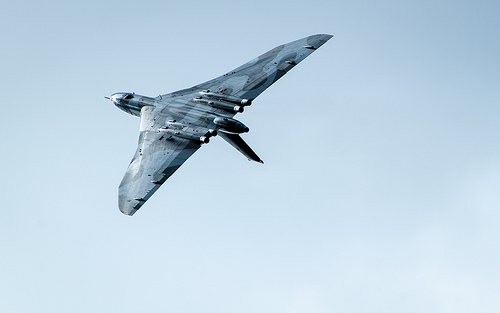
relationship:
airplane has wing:
[104, 34, 334, 216] [117, 116, 213, 217]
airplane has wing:
[104, 34, 334, 216] [191, 34, 332, 110]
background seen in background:
[0, 0, 499, 313] [1, 1, 483, 311]